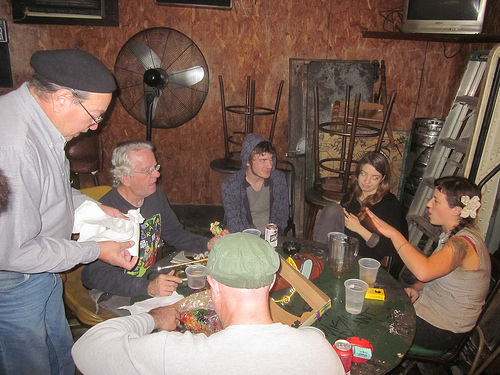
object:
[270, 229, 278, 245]
aluminum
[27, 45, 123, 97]
beret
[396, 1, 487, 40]
tv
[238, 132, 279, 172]
hood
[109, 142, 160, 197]
head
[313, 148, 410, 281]
woman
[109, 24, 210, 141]
fan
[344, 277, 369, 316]
cups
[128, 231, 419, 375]
table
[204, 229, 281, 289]
hat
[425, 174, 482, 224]
head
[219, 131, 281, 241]
man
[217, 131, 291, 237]
jacket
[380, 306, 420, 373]
edge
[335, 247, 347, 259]
glass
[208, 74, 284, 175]
stool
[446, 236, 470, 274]
tattoo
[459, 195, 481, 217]
flower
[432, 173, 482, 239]
hair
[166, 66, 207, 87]
blades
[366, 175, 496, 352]
woman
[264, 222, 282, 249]
can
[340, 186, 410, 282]
shirt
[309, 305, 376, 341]
writing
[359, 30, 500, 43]
shelf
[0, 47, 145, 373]
man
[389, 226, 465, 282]
arm